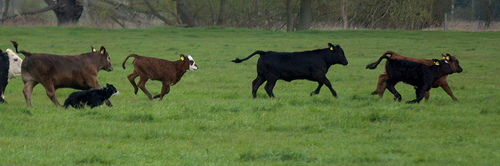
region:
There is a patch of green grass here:
[248, 100, 268, 142]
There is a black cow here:
[253, 41, 301, 98]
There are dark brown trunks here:
[177, 4, 196, 27]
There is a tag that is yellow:
[176, 53, 189, 65]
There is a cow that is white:
[9, 50, 26, 82]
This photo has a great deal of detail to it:
[141, 26, 286, 148]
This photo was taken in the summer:
[123, 29, 218, 153]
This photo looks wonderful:
[164, 35, 244, 160]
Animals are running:
[7, 28, 473, 143]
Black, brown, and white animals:
[12, 21, 483, 139]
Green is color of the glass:
[127, 106, 362, 151]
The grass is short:
[165, 100, 406, 156]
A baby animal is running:
[53, 77, 130, 117]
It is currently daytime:
[7, 10, 472, 160]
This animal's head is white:
[0, 36, 35, 84]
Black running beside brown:
[360, 32, 471, 117]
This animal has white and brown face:
[170, 42, 225, 88]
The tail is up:
[218, 39, 281, 76]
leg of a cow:
[17, 72, 37, 112]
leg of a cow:
[39, 75, 70, 112]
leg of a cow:
[260, 77, 280, 113]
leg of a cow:
[243, 71, 268, 116]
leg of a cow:
[134, 62, 165, 113]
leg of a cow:
[320, 80, 346, 99]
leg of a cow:
[374, 79, 414, 108]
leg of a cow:
[408, 79, 440, 110]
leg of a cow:
[151, 73, 173, 108]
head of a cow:
[320, 27, 360, 69]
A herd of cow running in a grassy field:
[4, 22, 475, 127]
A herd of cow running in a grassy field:
[5, 30, 473, 120]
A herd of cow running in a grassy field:
[5, 35, 481, 115]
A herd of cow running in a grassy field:
[7, 35, 475, 126]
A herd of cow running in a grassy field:
[2, 39, 472, 119]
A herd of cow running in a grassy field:
[7, 31, 470, 116]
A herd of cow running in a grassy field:
[4, 31, 478, 121]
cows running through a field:
[6, 3, 484, 149]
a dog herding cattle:
[64, 76, 156, 122]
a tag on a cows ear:
[322, 39, 334, 55]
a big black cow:
[226, 34, 353, 103]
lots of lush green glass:
[186, 105, 271, 150]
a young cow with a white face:
[121, 48, 222, 114]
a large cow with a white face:
[3, 46, 27, 81]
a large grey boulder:
[75, 4, 164, 43]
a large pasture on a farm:
[3, 15, 484, 162]